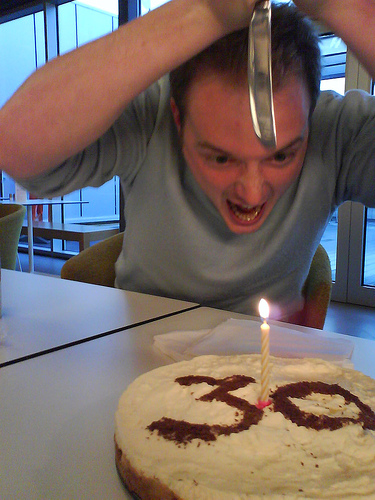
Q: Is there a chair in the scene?
A: Yes, there is a chair.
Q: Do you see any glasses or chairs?
A: Yes, there is a chair.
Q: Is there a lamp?
A: No, there are no lamps.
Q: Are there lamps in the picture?
A: No, there are no lamps.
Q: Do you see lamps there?
A: No, there are no lamps.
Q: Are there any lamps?
A: No, there are no lamps.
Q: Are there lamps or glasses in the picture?
A: No, there are no lamps or glasses.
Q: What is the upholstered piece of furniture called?
A: The piece of furniture is a chair.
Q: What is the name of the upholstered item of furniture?
A: The piece of furniture is a chair.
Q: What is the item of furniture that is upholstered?
A: The piece of furniture is a chair.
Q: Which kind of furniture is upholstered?
A: The furniture is a chair.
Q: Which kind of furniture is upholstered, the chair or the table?
A: The chair is upholstered.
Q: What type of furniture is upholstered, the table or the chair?
A: The chair is upholstered.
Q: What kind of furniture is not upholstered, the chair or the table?
A: The table is not upholstered.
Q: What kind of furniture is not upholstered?
A: The furniture is a table.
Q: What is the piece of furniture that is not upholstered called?
A: The piece of furniture is a table.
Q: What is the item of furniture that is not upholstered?
A: The piece of furniture is a table.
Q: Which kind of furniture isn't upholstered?
A: The furniture is a table.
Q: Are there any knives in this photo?
A: Yes, there is a knife.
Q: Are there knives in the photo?
A: Yes, there is a knife.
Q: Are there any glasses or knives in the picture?
A: Yes, there is a knife.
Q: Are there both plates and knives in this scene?
A: No, there is a knife but no plates.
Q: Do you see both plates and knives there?
A: No, there is a knife but no plates.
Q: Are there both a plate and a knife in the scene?
A: No, there is a knife but no plates.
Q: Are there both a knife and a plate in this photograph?
A: No, there is a knife but no plates.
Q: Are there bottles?
A: No, there are no bottles.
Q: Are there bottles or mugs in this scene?
A: No, there are no bottles or mugs.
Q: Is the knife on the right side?
A: Yes, the knife is on the right of the image.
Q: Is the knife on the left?
A: No, the knife is on the right of the image.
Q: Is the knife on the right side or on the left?
A: The knife is on the right of the image.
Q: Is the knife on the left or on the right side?
A: The knife is on the right of the image.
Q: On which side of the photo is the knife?
A: The knife is on the right of the image.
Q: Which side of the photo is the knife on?
A: The knife is on the right of the image.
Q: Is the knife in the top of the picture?
A: Yes, the knife is in the top of the image.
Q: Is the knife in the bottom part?
A: No, the knife is in the top of the image.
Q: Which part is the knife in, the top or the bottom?
A: The knife is in the top of the image.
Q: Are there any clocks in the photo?
A: No, there are no clocks.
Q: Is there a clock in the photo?
A: No, there are no clocks.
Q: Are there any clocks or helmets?
A: No, there are no clocks or helmets.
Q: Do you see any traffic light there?
A: No, there are no traffic lights.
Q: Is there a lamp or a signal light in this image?
A: No, there are no traffic lights or lamps.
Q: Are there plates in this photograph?
A: No, there are no plates.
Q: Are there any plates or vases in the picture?
A: No, there are no plates or vases.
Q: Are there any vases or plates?
A: No, there are no plates or vases.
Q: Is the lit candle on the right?
A: Yes, the candle is on the right of the image.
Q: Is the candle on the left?
A: No, the candle is on the right of the image.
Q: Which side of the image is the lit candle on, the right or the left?
A: The candle is on the right of the image.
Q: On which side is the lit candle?
A: The candle is on the right of the image.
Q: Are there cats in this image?
A: No, there are no cats.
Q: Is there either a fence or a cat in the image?
A: No, there are no cats or fences.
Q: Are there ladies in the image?
A: No, there are no ladies.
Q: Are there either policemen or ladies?
A: No, there are no ladies or policemen.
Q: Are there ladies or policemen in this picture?
A: No, there are no ladies or policemen.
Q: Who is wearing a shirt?
A: The man is wearing a shirt.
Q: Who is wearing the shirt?
A: The man is wearing a shirt.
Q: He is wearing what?
A: The man is wearing a shirt.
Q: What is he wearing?
A: The man is wearing a shirt.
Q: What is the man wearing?
A: The man is wearing a shirt.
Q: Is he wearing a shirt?
A: Yes, the man is wearing a shirt.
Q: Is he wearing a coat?
A: No, the man is wearing a shirt.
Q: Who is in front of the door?
A: The man is in front of the door.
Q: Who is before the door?
A: The man is in front of the door.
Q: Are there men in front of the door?
A: Yes, there is a man in front of the door.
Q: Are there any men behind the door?
A: No, the man is in front of the door.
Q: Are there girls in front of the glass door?
A: No, there is a man in front of the door.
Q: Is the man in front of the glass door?
A: Yes, the man is in front of the door.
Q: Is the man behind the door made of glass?
A: No, the man is in front of the door.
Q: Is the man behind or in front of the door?
A: The man is in front of the door.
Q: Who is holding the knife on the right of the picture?
A: The man is holding the knife.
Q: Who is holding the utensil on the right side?
A: The man is holding the knife.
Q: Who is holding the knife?
A: The man is holding the knife.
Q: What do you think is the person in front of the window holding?
A: The man is holding the knife.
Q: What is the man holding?
A: The man is holding the knife.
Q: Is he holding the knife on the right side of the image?
A: Yes, the man is holding the knife.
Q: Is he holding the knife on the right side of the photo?
A: Yes, the man is holding the knife.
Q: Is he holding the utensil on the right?
A: Yes, the man is holding the knife.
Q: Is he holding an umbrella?
A: No, the man is holding the knife.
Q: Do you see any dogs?
A: No, there are no dogs.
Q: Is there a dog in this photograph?
A: No, there are no dogs.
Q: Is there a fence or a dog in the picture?
A: No, there are no dogs or fences.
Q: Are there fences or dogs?
A: No, there are no dogs or fences.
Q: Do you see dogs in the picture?
A: No, there are no dogs.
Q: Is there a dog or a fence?
A: No, there are no dogs or fences.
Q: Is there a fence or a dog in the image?
A: No, there are no dogs or fences.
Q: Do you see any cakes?
A: Yes, there is a cake.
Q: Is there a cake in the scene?
A: Yes, there is a cake.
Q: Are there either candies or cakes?
A: Yes, there is a cake.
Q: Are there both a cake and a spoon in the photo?
A: No, there is a cake but no spoons.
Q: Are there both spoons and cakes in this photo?
A: No, there is a cake but no spoons.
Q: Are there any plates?
A: No, there are no plates.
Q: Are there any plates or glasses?
A: No, there are no plates or glasses.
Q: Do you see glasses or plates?
A: No, there are no plates or glasses.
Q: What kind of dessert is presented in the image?
A: The dessert is a cake.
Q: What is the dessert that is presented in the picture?
A: The dessert is a cake.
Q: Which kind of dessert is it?
A: The dessert is a cake.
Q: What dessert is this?
A: This is a cake.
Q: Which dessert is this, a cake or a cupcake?
A: This is a cake.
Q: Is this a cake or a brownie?
A: This is a cake.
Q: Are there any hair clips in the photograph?
A: No, there are no hair clips.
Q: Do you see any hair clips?
A: No, there are no hair clips.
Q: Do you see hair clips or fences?
A: No, there are no hair clips or fences.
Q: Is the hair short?
A: Yes, the hair is short.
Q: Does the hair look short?
A: Yes, the hair is short.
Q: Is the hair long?
A: No, the hair is short.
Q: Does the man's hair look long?
A: No, the hair is short.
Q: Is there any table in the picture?
A: Yes, there is a table.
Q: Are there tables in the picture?
A: Yes, there is a table.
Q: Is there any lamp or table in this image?
A: Yes, there is a table.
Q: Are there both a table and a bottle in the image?
A: No, there is a table but no bottles.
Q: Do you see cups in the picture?
A: No, there are no cups.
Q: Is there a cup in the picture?
A: No, there are no cups.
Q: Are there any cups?
A: No, there are no cups.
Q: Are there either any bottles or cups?
A: No, there are no cups or bottles.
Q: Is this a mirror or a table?
A: This is a table.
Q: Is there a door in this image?
A: Yes, there is a door.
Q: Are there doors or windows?
A: Yes, there is a door.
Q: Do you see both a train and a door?
A: No, there is a door but no trains.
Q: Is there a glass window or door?
A: Yes, there is a glass door.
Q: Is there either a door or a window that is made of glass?
A: Yes, the door is made of glass.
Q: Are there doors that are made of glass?
A: Yes, there is a door that is made of glass.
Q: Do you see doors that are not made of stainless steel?
A: Yes, there is a door that is made of glass.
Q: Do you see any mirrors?
A: No, there are no mirrors.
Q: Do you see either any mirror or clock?
A: No, there are no mirrors or clocks.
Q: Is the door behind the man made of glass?
A: Yes, the door is made of glass.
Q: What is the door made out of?
A: The door is made of glass.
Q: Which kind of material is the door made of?
A: The door is made of glass.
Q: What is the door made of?
A: The door is made of glass.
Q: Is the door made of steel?
A: No, the door is made of glass.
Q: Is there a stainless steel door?
A: No, there is a door but it is made of glass.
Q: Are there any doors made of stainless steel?
A: No, there is a door but it is made of glass.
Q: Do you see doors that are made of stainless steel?
A: No, there is a door but it is made of glass.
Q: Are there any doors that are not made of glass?
A: No, there is a door but it is made of glass.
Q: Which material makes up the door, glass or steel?
A: The door is made of glass.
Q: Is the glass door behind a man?
A: Yes, the door is behind a man.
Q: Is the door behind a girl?
A: No, the door is behind a man.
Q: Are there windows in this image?
A: Yes, there is a window.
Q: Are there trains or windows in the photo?
A: Yes, there is a window.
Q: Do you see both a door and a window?
A: Yes, there are both a window and a door.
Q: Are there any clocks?
A: No, there are no clocks.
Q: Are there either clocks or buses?
A: No, there are no clocks or buses.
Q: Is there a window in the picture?
A: Yes, there is a window.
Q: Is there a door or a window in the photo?
A: Yes, there is a window.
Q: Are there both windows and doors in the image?
A: Yes, there are both a window and a door.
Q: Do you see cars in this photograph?
A: No, there are no cars.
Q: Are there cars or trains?
A: No, there are no cars or trains.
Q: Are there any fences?
A: No, there are no fences.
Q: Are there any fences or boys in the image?
A: No, there are no fences or boys.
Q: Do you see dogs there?
A: No, there are no dogs.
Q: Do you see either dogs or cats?
A: No, there are no dogs or cats.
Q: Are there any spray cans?
A: No, there are no spray cans.